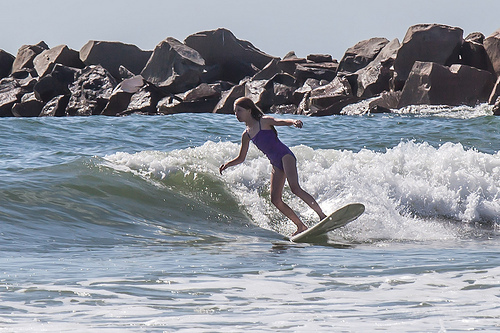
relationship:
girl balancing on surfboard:
[217, 95, 330, 236] [289, 202, 369, 240]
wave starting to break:
[100, 128, 497, 246] [90, 134, 497, 323]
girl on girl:
[276, 200, 367, 242] [217, 95, 330, 236]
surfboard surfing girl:
[289, 202, 369, 240] [217, 95, 330, 236]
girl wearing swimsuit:
[217, 95, 330, 236] [250, 127, 292, 170]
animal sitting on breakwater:
[126, 74, 179, 117] [136, 137, 493, 248]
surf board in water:
[276, 200, 367, 242] [199, 220, 336, 296]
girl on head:
[217, 95, 330, 236] [227, 94, 260, 129]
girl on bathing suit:
[217, 95, 330, 236] [246, 102, 292, 180]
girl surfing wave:
[217, 100, 329, 242] [147, 205, 497, 330]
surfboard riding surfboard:
[289, 202, 369, 240] [289, 202, 369, 240]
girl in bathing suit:
[217, 100, 329, 242] [256, 130, 292, 173]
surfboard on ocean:
[289, 202, 369, 240] [143, 242, 473, 318]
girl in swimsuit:
[217, 95, 330, 236] [249, 127, 289, 173]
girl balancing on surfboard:
[217, 95, 330, 236] [270, 195, 362, 246]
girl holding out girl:
[217, 95, 330, 236] [217, 95, 330, 236]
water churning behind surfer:
[0, 105, 500, 333] [210, 96, 336, 242]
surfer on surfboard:
[276, 200, 367, 242] [289, 202, 369, 240]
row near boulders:
[5, 24, 499, 100] [85, 33, 474, 119]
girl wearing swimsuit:
[217, 95, 330, 236] [253, 131, 293, 171]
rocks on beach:
[5, 24, 499, 100] [53, 103, 495, 124]